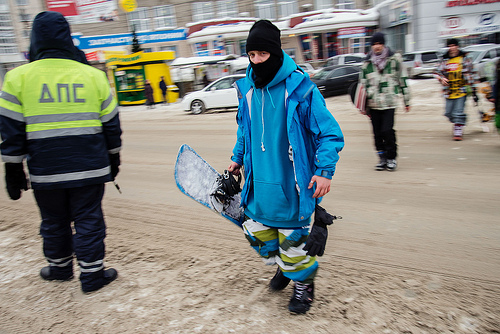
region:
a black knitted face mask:
[246, 20, 282, 91]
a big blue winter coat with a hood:
[229, 44, 343, 234]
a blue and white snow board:
[172, 143, 243, 234]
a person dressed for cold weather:
[349, 33, 415, 172]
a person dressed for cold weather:
[2, 12, 129, 299]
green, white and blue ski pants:
[238, 212, 323, 284]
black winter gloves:
[301, 194, 338, 257]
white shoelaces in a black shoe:
[290, 282, 310, 300]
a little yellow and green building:
[104, 47, 176, 104]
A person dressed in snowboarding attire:
[172, 18, 343, 313]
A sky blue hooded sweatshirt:
[242, 48, 309, 226]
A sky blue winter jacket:
[231, 67, 345, 222]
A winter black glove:
[303, 196, 343, 256]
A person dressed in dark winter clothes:
[0, 11, 122, 292]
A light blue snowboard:
[174, 144, 246, 229]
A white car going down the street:
[182, 73, 247, 114]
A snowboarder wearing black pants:
[350, 33, 411, 173]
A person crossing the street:
[435, 38, 478, 140]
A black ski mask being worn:
[246, 20, 282, 87]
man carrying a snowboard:
[168, 7, 358, 309]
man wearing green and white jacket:
[352, 22, 414, 177]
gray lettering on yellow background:
[36, 82, 91, 104]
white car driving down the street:
[175, 72, 240, 116]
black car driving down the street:
[307, 59, 355, 99]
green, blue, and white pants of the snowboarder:
[244, 213, 310, 287]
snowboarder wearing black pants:
[350, 39, 412, 169]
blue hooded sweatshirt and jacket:
[222, 76, 336, 228]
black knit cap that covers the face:
[235, 11, 287, 84]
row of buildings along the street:
[0, 3, 498, 82]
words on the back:
[41, 78, 85, 106]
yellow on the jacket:
[17, 73, 52, 81]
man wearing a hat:
[33, 8, 62, 44]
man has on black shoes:
[107, 269, 113, 276]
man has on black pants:
[84, 197, 104, 234]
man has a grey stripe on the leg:
[81, 262, 99, 266]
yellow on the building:
[148, 70, 163, 75]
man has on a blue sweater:
[262, 127, 273, 175]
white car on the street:
[210, 98, 235, 105]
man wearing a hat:
[370, 30, 382, 45]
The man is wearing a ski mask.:
[223, 24, 283, 81]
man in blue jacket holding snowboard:
[171, 16, 348, 319]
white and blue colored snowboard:
[161, 132, 252, 228]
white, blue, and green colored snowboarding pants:
[231, 204, 321, 284]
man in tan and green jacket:
[335, 27, 412, 174]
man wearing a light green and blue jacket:
[1, 7, 131, 292]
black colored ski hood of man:
[233, 12, 285, 89]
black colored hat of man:
[366, 31, 386, 45]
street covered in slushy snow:
[32, 44, 493, 281]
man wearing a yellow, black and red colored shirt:
[433, 38, 475, 146]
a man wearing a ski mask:
[235, 25, 295, 92]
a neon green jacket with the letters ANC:
[15, 54, 114, 136]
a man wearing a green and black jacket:
[0, 12, 134, 216]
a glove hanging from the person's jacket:
[292, 176, 354, 291]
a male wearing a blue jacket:
[232, 22, 339, 197]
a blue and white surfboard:
[163, 136, 253, 237]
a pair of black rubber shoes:
[258, 261, 325, 328]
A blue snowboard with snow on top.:
[170, 144, 245, 228]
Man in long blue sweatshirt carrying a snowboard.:
[225, 19, 345, 314]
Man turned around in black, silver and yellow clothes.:
[0, 12, 123, 291]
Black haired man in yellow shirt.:
[437, 35, 472, 140]